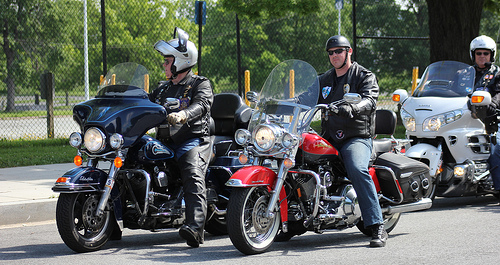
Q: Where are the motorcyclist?
A: On road.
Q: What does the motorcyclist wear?
A: Black outfit.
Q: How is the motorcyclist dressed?
A: Helmet and leather vest.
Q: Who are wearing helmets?
A: The men.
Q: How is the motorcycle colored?
A: Red.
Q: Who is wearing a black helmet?
A: The guy.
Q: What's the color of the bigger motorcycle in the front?
A: Black.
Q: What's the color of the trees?
A: Green.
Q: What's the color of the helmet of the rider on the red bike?
A: Black.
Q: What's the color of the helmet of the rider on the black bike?
A: Silver.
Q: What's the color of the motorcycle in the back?
A: White.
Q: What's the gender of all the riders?
A: Male.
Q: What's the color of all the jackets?
A: Black.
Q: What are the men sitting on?
A: Motorcycles.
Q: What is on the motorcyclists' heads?
A: Helmets.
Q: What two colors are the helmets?
A: Black and white.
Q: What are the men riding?
A: Motorcycles.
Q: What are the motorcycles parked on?
A: The street.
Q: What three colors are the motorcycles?
A: Red, black and white.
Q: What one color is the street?
A: Grey.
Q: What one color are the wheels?
A: Black.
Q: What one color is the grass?
A: Green.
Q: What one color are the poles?
A: Yellow.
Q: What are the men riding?
A: Motorcycles.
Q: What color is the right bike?
A: Red.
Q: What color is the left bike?
A: Black.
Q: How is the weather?
A: Sunny.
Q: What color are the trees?
A: Green.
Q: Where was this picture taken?
A: A street.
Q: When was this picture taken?
A: Daytime.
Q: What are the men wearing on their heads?
A: Helmets.